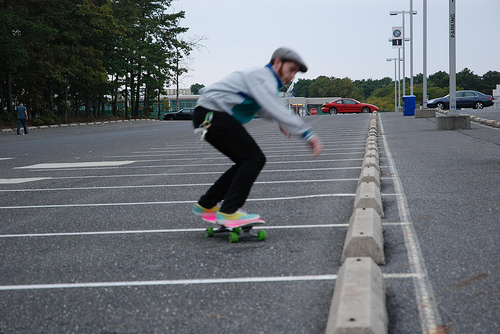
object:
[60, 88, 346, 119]
building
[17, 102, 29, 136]
man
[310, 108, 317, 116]
sign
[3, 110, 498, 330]
lot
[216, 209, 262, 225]
shoes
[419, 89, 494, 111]
car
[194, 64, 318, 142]
gray sweatshirt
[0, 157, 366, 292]
lines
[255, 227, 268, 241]
wheel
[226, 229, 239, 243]
wheel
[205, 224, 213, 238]
wheel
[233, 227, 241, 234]
wheel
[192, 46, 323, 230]
man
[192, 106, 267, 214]
pants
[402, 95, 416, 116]
container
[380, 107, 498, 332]
walkway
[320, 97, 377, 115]
car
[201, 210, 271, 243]
skateboard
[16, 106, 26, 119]
shirt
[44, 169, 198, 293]
paint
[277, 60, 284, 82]
burns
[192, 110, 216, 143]
keys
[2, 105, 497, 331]
parking lot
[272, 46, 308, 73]
hat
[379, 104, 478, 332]
walkway